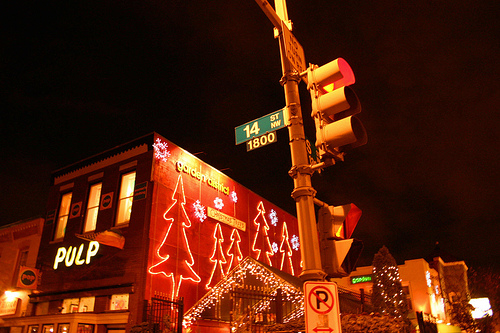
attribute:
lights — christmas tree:
[146, 167, 203, 313]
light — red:
[302, 50, 387, 144]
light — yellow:
[298, 55, 396, 174]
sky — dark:
[9, 13, 250, 133]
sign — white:
[265, 262, 363, 327]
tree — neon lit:
[194, 213, 264, 319]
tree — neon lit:
[245, 208, 314, 283]